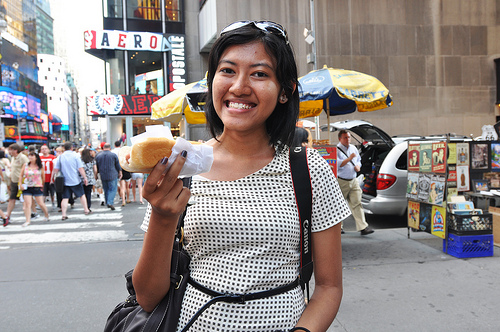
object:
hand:
[140, 149, 196, 223]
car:
[317, 119, 476, 217]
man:
[332, 127, 378, 234]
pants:
[337, 178, 371, 232]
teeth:
[243, 104, 246, 108]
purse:
[102, 145, 210, 331]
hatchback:
[319, 118, 398, 207]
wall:
[215, 1, 498, 147]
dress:
[135, 137, 347, 331]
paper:
[164, 136, 217, 180]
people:
[91, 141, 122, 211]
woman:
[19, 146, 53, 229]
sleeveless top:
[21, 164, 43, 188]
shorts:
[22, 186, 43, 197]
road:
[0, 193, 500, 331]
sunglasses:
[216, 18, 289, 45]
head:
[201, 21, 299, 131]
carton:
[441, 231, 497, 259]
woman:
[127, 19, 355, 331]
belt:
[186, 274, 303, 306]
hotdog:
[117, 135, 210, 175]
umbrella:
[298, 63, 397, 150]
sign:
[83, 29, 170, 58]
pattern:
[139, 139, 349, 331]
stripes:
[0, 229, 130, 243]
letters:
[148, 33, 159, 49]